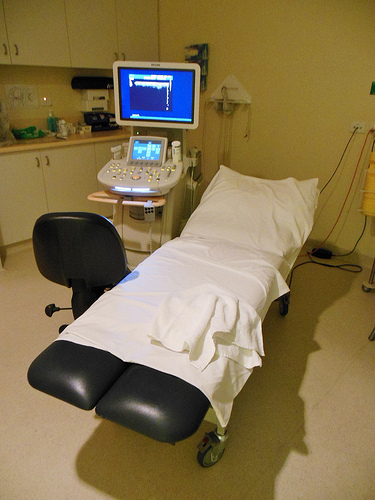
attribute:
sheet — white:
[199, 214, 262, 286]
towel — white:
[187, 300, 269, 356]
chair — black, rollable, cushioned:
[30, 196, 131, 311]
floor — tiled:
[287, 414, 361, 462]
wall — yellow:
[235, 30, 348, 158]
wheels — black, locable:
[188, 423, 247, 474]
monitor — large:
[114, 51, 200, 135]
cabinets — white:
[23, 9, 189, 52]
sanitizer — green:
[37, 116, 62, 134]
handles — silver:
[2, 45, 22, 57]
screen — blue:
[126, 79, 187, 108]